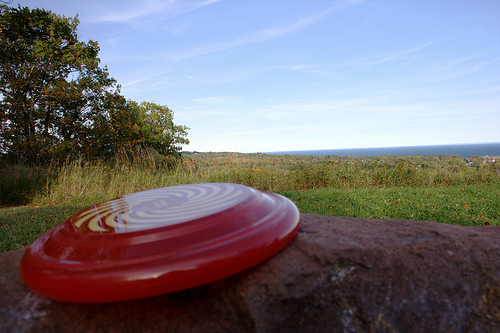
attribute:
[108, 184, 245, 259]
frisbee — red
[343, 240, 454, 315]
rock — brown, white, black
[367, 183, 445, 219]
grass — green, brown, long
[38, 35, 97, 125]
tree — green, brown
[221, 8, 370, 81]
sky — blue